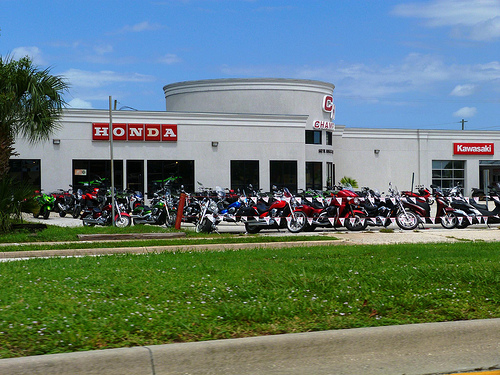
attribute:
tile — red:
[161, 124, 177, 140]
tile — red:
[145, 124, 159, 141]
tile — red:
[128, 124, 145, 139]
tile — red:
[111, 121, 128, 141]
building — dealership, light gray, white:
[0, 79, 499, 220]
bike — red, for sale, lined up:
[248, 191, 315, 233]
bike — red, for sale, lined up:
[301, 191, 367, 229]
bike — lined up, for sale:
[354, 187, 421, 231]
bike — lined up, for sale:
[391, 182, 458, 230]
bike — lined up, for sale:
[109, 188, 175, 227]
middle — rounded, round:
[162, 77, 335, 120]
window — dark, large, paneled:
[228, 159, 263, 193]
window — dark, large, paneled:
[269, 159, 297, 188]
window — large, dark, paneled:
[149, 158, 195, 197]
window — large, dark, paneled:
[74, 158, 127, 193]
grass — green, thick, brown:
[0, 238, 495, 355]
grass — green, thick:
[0, 223, 331, 250]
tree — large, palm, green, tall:
[0, 55, 68, 232]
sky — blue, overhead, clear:
[0, 0, 498, 129]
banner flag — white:
[237, 194, 248, 205]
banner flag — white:
[250, 196, 258, 203]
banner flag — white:
[238, 216, 250, 226]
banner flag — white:
[264, 216, 272, 228]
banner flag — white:
[203, 213, 218, 224]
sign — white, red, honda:
[90, 123, 178, 142]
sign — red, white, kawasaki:
[448, 142, 495, 157]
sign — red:
[319, 91, 336, 112]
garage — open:
[479, 163, 499, 199]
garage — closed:
[3, 159, 43, 205]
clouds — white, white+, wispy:
[0, 1, 497, 119]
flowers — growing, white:
[0, 264, 396, 344]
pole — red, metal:
[172, 190, 185, 231]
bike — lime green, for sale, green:
[30, 191, 59, 219]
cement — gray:
[0, 317, 497, 374]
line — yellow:
[460, 366, 496, 375]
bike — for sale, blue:
[196, 194, 263, 235]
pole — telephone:
[457, 117, 468, 130]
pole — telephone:
[113, 100, 119, 108]